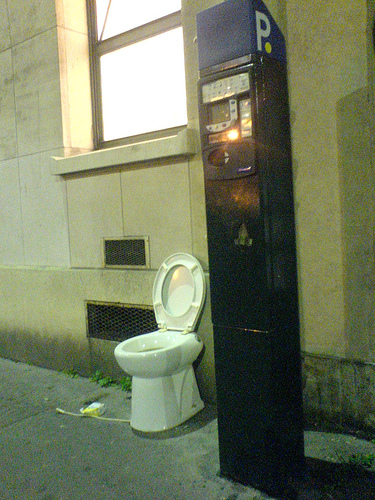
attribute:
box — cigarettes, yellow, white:
[81, 402, 109, 415]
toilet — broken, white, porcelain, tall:
[113, 252, 207, 433]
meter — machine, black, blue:
[198, 1, 293, 478]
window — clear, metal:
[86, 1, 184, 151]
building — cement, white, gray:
[4, 0, 371, 359]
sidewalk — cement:
[1, 357, 374, 499]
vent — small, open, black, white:
[100, 238, 148, 269]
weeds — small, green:
[65, 369, 131, 388]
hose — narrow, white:
[54, 411, 132, 424]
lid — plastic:
[151, 253, 206, 333]